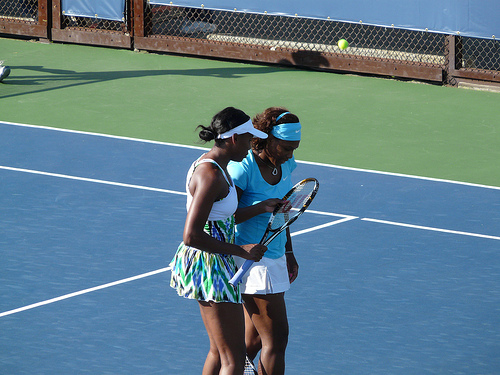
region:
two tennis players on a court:
[130, 97, 332, 343]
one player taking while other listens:
[145, 87, 340, 349]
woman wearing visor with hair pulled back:
[186, 95, 267, 181]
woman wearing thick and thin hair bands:
[246, 100, 301, 171]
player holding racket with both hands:
[160, 105, 315, 340]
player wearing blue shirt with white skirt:
[240, 96, 325, 311]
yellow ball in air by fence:
[241, 11, 441, 102]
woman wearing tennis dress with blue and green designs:
[165, 100, 245, 322]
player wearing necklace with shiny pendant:
[250, 120, 297, 200]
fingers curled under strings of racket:
[252, 171, 335, 234]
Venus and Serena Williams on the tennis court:
[167, 105, 319, 373]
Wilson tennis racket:
[231, 177, 321, 285]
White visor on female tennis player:
[214, 116, 268, 140]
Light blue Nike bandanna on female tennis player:
[273, 110, 303, 142]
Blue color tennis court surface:
[335, 260, 466, 345]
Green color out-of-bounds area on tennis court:
[340, 86, 462, 153]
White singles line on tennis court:
[362, 216, 498, 243]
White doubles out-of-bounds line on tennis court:
[357, 163, 498, 198]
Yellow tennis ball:
[337, 37, 349, 49]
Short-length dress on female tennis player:
[168, 154, 243, 306]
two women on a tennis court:
[156, 103, 313, 370]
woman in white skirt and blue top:
[246, 107, 313, 373]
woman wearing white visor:
[169, 110, 254, 373]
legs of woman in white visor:
[199, 275, 249, 373]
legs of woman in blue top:
[241, 270, 293, 372]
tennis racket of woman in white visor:
[224, 176, 320, 286]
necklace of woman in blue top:
[258, 159, 284, 176]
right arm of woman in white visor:
[183, 173, 265, 262]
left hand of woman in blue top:
[283, 256, 303, 282]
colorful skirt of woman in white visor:
[172, 214, 247, 309]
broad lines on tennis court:
[46, 265, 163, 324]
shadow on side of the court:
[54, 42, 326, 111]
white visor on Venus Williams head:
[221, 113, 276, 150]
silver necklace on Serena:
[262, 159, 296, 178]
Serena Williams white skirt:
[246, 253, 315, 298]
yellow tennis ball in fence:
[323, 27, 386, 70]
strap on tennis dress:
[163, 145, 252, 192]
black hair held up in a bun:
[187, 100, 238, 166]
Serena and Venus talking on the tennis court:
[155, 63, 355, 365]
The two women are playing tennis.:
[160, 92, 361, 372]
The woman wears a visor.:
[204, 105, 271, 145]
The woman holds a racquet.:
[212, 172, 324, 292]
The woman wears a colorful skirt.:
[155, 216, 250, 306]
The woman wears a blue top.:
[225, 151, 317, 266]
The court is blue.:
[0, 185, 496, 373]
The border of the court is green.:
[0, 40, 498, 191]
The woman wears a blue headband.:
[264, 109, 313, 144]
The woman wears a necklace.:
[265, 155, 289, 180]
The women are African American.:
[165, 98, 337, 373]